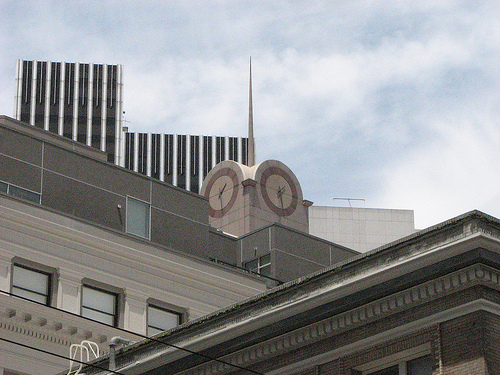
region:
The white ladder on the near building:
[65, 337, 100, 372]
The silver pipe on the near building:
[101, 334, 136, 372]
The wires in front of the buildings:
[3, 286, 270, 373]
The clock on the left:
[202, 167, 241, 219]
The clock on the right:
[260, 161, 305, 225]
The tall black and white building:
[12, 55, 252, 196]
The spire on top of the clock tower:
[242, 55, 262, 170]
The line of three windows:
[7, 252, 189, 342]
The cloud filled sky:
[0, 0, 497, 229]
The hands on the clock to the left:
[213, 178, 232, 220]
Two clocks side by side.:
[201, 164, 301, 221]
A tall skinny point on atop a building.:
[243, 53, 258, 163]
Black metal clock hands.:
[273, 182, 292, 218]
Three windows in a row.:
[8, 255, 188, 342]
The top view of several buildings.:
[0, 55, 499, 372]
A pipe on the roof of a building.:
[105, 336, 136, 373]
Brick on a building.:
[231, 280, 498, 373]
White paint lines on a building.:
[2, 140, 123, 209]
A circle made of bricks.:
[257, 163, 300, 220]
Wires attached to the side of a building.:
[0, 285, 252, 373]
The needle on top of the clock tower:
[243, 52, 258, 174]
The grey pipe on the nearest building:
[101, 335, 138, 373]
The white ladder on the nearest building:
[67, 337, 102, 373]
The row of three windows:
[7, 249, 186, 349]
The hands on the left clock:
[215, 175, 230, 211]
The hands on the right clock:
[275, 175, 287, 216]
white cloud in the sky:
[328, 34, 418, 101]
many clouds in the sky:
[295, 19, 471, 157]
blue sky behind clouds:
[321, 121, 408, 182]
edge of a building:
[335, 205, 487, 282]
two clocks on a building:
[196, 155, 302, 225]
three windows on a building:
[2, 270, 215, 337]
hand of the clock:
[261, 180, 298, 217]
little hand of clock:
[216, 176, 231, 196]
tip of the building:
[224, 44, 273, 139]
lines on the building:
[16, 145, 83, 198]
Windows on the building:
[9, 260, 182, 335]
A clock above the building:
[208, 167, 297, 217]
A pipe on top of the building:
[108, 335, 133, 368]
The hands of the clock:
[273, 183, 287, 211]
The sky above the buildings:
[0, 0, 497, 207]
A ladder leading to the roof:
[68, 340, 98, 373]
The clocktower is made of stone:
[202, 157, 306, 232]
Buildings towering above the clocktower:
[18, 60, 245, 188]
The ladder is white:
[66, 339, 97, 374]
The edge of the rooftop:
[68, 210, 498, 374]